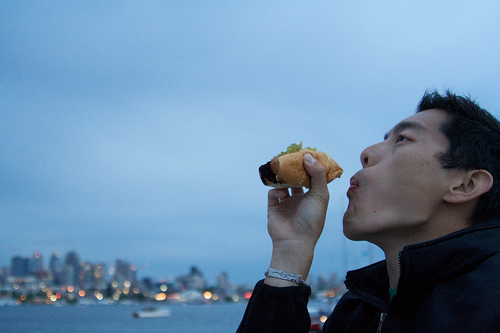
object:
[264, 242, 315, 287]
wrist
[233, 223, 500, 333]
jacket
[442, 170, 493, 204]
ear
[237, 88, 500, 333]
man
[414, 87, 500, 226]
hair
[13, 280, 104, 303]
light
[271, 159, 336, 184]
dog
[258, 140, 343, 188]
bun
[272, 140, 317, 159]
lettuce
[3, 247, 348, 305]
buildings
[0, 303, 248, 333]
river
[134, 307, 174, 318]
boat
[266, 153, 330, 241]
hand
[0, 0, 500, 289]
sky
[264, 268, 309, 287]
bracelet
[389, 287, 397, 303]
shirt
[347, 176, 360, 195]
mouth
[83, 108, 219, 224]
clouds